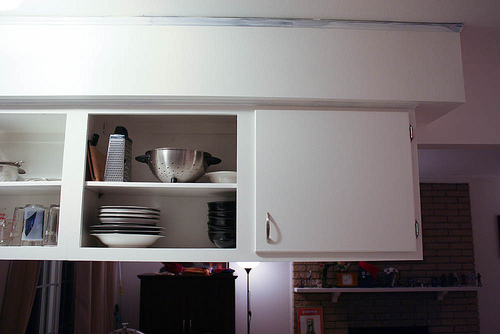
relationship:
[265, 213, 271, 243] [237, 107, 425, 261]
handle for cabinet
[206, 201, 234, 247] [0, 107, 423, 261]
bowls in cupboard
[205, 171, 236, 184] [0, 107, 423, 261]
bowl in cupboard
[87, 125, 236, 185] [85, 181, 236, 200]
items on shelf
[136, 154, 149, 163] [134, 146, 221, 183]
handle on strainer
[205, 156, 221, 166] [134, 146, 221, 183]
handle on strainer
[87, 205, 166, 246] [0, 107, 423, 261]
plates in cabinet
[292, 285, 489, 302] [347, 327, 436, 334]
shelf over fireplace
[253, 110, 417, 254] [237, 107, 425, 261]
door on cabinet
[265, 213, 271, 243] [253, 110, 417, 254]
handle on door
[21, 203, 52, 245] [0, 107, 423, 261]
glass in cabinet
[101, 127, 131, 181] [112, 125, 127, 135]
grater with handle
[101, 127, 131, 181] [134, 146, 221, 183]
grater next to strainer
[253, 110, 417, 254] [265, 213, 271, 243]
door with handle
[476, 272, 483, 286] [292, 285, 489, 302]
figure on shelf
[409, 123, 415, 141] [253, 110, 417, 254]
hinge on door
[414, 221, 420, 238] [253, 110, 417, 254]
hinge on door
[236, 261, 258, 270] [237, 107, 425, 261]
light under cabinet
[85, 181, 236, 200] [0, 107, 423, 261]
shelf in cabinet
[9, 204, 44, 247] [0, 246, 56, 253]
mug on shelf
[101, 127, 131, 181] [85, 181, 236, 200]
grater on shelf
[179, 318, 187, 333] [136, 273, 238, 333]
handle on cabinet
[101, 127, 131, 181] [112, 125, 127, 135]
cheese shredder with handle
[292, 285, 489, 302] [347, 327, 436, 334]
mantle on fireplace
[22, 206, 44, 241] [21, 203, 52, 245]
design on glass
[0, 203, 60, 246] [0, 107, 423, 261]
glasses in cabinet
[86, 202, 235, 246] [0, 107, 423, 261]
dishes in cabinet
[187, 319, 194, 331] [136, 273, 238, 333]
handle on cabinet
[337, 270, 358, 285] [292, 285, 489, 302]
clock on shelf